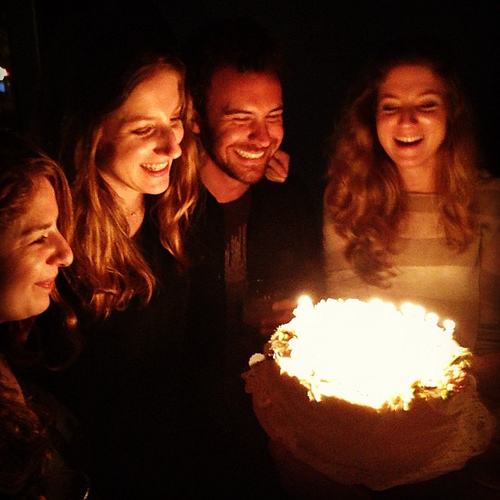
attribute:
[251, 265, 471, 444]
cake — candles 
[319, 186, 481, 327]
woman — c gray and white sweater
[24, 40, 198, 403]
man — drink 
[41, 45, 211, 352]
woman — blonde hair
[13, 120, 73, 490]
woman — striped 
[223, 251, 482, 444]
birthday cake — illuminated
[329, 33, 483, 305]
woman — long hair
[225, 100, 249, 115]
man — eyebrows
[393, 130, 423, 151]
mouth —  open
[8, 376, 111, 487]
shirt — burgandy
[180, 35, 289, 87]
man — black haired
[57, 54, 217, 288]
woman — long haired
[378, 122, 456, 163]
woman — smiling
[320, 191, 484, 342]
shirt — striped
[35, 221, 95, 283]
nose — pointed